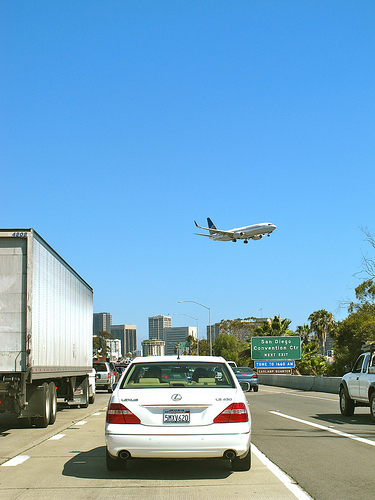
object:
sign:
[251, 336, 300, 359]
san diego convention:
[253, 338, 299, 351]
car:
[104, 354, 251, 471]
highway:
[0, 377, 374, 499]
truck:
[338, 349, 375, 425]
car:
[228, 367, 259, 392]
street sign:
[254, 361, 295, 368]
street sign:
[257, 367, 292, 375]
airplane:
[192, 217, 277, 245]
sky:
[0, 1, 373, 208]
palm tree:
[253, 314, 291, 336]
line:
[0, 410, 102, 472]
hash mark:
[1, 452, 31, 468]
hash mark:
[47, 432, 65, 440]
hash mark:
[75, 418, 88, 425]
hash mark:
[92, 410, 102, 416]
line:
[267, 408, 375, 448]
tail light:
[213, 402, 249, 423]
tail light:
[106, 403, 141, 425]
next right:
[264, 351, 289, 357]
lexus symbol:
[171, 393, 182, 401]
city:
[92, 313, 303, 372]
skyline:
[93, 305, 374, 328]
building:
[163, 326, 196, 355]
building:
[148, 315, 171, 340]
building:
[141, 339, 166, 355]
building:
[108, 325, 137, 357]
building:
[93, 312, 112, 338]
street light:
[173, 312, 201, 356]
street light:
[178, 299, 212, 356]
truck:
[0, 227, 96, 428]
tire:
[33, 382, 51, 429]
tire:
[50, 382, 57, 426]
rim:
[45, 391, 49, 419]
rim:
[52, 395, 57, 417]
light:
[106, 409, 130, 414]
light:
[222, 408, 247, 415]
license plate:
[162, 409, 190, 424]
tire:
[106, 446, 127, 470]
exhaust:
[117, 449, 130, 462]